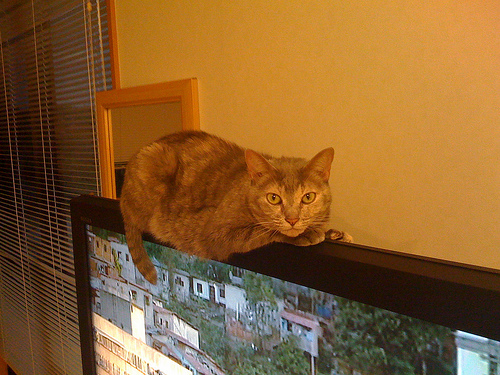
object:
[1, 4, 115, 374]
blinds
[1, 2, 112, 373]
window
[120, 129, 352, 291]
cat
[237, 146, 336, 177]
ears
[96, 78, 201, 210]
mirror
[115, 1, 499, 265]
wall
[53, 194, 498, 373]
television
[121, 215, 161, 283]
tail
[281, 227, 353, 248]
paws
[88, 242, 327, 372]
houses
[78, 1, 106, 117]
pull string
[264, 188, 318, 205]
eye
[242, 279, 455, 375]
tree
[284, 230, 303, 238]
chin